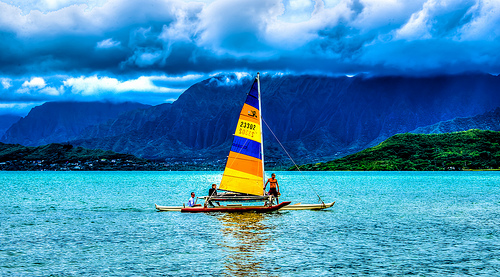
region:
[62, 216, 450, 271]
The lake water is very calm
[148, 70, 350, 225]
People on a sail boat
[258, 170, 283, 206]
The man standing on a boat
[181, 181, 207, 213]
The man is sitting in the boat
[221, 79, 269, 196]
The sail on the boat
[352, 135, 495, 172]
The grass on the mountain is green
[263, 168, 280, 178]
The head of the man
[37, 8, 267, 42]
The clouds are in the sky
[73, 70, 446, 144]
The mountains are majestic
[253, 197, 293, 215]
The end of the boat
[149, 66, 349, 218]
a sail boat in the water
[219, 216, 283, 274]
a reflection in the water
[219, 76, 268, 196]
a yellow blue and orange sail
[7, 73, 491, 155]
blue mountains in the distance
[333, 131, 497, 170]
a green grassy hill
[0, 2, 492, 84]
a cloudy sky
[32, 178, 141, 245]
a crystal clear water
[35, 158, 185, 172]
a town on shore line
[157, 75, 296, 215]
three people in a sail boat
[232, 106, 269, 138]
a number on the sail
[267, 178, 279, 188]
Orange shirt on sailor.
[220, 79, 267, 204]
Colorful sail on boat.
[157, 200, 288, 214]
Small sailboat in water.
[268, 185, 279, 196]
Black shorts on sailor.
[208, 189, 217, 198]
Black shirt on sailor.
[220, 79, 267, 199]
Multiple colored sail on boat.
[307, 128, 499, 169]
Grassy hillside on island.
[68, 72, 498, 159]
Mountain range in distance.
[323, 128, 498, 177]
Green hillside by island.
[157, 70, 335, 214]
Group of sailors in water.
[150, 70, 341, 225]
A sail boat in the foreground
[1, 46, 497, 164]
Mountains are in the background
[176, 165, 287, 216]
People are on a boat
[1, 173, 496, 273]
The water is blue in color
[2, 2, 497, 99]
Clouds are in the sky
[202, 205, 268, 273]
Boat's reflection is in the water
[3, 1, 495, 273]
Photo was taken in the daytime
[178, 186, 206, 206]
Man is wearing a white shirt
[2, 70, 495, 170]
Mountains are blue in color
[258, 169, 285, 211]
Person is standing on a boat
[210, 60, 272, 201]
THE SAIL IS VERY COLORFUL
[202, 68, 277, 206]
THE SAIL IS STRIPED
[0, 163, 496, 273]
THE WATER IS REFLECTING THE SKY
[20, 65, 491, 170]
THE MOUNTAIN IS LARGE AND TALL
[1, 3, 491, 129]
THE CLOUDS ARE PUFFY AND WHITE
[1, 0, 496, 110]
THE CLOUDS ARE TOUCHING THE TOP OF THE MOUNTAIN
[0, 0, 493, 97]
THE CLOUDS ARE FLUFFY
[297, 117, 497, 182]
THE HILL IS VERY GRASSY AND LUSH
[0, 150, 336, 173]
THE BUILDINGS ARE IN THE DISTANCE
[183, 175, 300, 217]
THE PEOPLE ARE SAILING